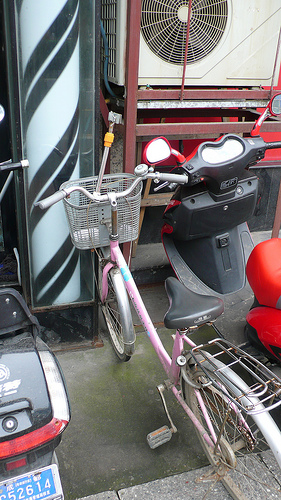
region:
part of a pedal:
[143, 427, 166, 447]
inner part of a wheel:
[236, 440, 258, 488]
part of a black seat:
[181, 302, 197, 318]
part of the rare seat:
[229, 372, 265, 400]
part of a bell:
[136, 166, 145, 175]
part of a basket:
[116, 203, 132, 221]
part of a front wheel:
[102, 302, 123, 336]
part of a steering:
[63, 166, 181, 186]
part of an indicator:
[30, 435, 55, 443]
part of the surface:
[108, 434, 138, 468]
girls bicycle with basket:
[27, 170, 267, 498]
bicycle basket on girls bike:
[51, 171, 168, 258]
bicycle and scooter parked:
[37, 118, 280, 489]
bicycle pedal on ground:
[134, 418, 189, 455]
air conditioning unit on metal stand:
[76, 0, 277, 93]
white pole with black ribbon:
[5, 0, 99, 316]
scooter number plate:
[0, 466, 75, 498]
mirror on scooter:
[138, 133, 180, 167]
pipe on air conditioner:
[95, 15, 131, 104]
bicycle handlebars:
[34, 161, 197, 225]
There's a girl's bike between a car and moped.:
[39, 157, 279, 499]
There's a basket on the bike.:
[49, 158, 152, 259]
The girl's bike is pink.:
[88, 228, 279, 469]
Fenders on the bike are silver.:
[183, 318, 280, 463]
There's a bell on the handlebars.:
[128, 161, 157, 182]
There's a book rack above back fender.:
[182, 332, 279, 415]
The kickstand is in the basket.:
[90, 109, 124, 215]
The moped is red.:
[131, 89, 279, 355]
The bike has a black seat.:
[158, 266, 228, 331]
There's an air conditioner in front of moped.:
[94, 0, 279, 104]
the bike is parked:
[36, 120, 269, 494]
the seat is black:
[158, 269, 223, 350]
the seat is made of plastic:
[162, 274, 249, 353]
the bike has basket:
[26, 158, 201, 263]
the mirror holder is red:
[133, 122, 277, 161]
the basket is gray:
[44, 174, 223, 265]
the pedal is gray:
[111, 403, 178, 451]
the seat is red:
[228, 221, 279, 279]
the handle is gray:
[20, 173, 89, 234]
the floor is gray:
[77, 422, 136, 477]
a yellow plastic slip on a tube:
[99, 131, 116, 146]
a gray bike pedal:
[140, 420, 169, 449]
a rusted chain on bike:
[220, 406, 253, 442]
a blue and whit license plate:
[5, 465, 54, 497]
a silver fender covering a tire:
[115, 278, 133, 357]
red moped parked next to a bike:
[181, 138, 278, 329]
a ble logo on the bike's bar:
[121, 265, 130, 286]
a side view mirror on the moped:
[140, 137, 178, 166]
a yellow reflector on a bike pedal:
[148, 427, 176, 436]